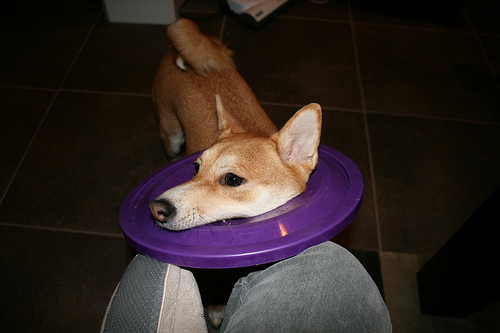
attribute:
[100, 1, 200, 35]
wall — white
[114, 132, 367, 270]
disc — purple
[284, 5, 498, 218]
floor — brown, tiled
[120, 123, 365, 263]
frisbee — purple 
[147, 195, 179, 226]
nose — black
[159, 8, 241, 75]
tail — curlty 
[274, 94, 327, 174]
ear — pointed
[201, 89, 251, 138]
ear — pointed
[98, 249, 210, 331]
shoe — person's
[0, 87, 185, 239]
tile — ceramic 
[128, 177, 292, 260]
frisbee — purple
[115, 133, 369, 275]
frisbee — purple 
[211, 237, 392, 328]
jeans — grey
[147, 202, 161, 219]
tip — pink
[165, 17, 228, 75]
tail — curly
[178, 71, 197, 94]
fur — brown